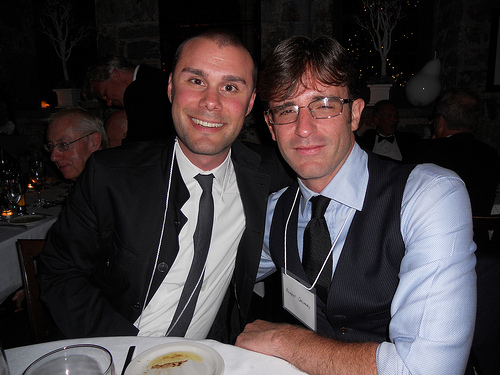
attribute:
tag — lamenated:
[280, 268, 317, 332]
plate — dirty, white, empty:
[126, 340, 225, 374]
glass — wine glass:
[21, 344, 115, 374]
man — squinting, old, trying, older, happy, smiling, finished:
[235, 36, 476, 374]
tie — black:
[166, 173, 216, 339]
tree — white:
[38, 0, 94, 81]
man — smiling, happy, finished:
[39, 24, 296, 346]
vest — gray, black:
[269, 151, 417, 354]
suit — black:
[36, 135, 298, 347]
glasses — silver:
[265, 98, 353, 126]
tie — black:
[303, 195, 332, 307]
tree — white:
[358, 0, 403, 82]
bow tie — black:
[376, 134, 398, 145]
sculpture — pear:
[406, 49, 443, 108]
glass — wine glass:
[3, 178, 24, 221]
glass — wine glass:
[26, 164, 49, 208]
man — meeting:
[77, 52, 175, 144]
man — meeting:
[102, 108, 129, 148]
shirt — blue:
[377, 162, 479, 374]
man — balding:
[42, 108, 108, 183]